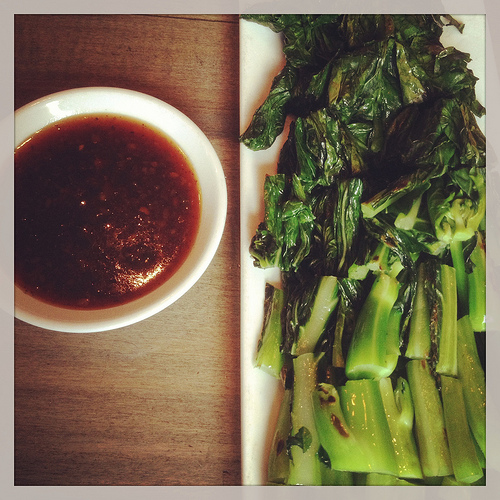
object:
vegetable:
[434, 262, 461, 379]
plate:
[238, 13, 487, 487]